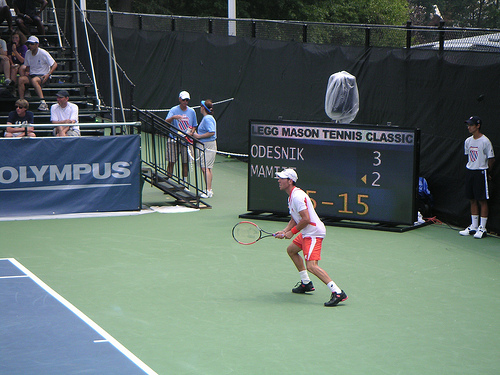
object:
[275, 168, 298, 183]
hat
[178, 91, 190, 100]
hat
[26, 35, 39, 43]
hat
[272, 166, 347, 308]
man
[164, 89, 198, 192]
man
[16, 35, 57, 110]
man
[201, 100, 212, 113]
visor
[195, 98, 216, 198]
woman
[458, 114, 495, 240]
man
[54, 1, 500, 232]
wall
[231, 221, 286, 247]
tennis racket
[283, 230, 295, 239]
hand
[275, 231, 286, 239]
hand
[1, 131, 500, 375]
tennis court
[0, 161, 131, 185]
olympus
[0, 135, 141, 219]
sign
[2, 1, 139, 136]
stands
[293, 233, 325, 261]
shorts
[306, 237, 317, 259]
stripe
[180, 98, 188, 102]
sun glasses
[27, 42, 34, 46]
sun glasses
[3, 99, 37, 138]
man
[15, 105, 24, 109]
sun glasses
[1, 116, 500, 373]
court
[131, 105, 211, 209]
stairs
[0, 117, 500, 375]
floor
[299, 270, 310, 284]
sock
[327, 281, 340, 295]
sock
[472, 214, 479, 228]
sock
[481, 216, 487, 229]
sock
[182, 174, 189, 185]
sock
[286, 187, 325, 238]
shirt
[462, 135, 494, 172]
shirt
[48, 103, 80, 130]
shirt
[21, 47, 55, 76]
shirt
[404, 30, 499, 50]
tent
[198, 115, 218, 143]
blouse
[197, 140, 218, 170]
shorts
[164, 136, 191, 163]
shorts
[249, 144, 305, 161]
word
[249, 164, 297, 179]
word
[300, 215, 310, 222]
elbow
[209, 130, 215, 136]
elbow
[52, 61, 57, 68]
elbow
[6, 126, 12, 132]
elbow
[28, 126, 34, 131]
elbow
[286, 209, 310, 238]
skin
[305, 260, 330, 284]
skin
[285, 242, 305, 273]
skin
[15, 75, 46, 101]
skin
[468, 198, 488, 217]
skin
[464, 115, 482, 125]
cap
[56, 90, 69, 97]
cap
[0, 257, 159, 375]
line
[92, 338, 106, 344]
line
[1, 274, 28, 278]
line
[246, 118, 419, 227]
score board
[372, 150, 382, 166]
number 3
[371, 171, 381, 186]
number 2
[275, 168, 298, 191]
head